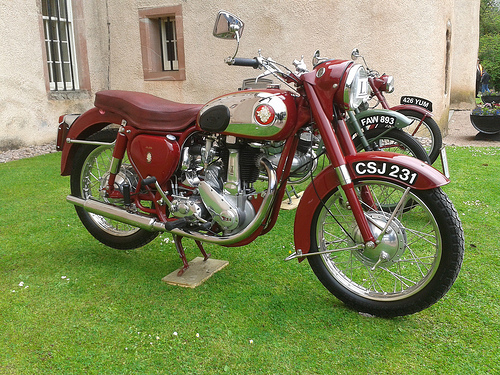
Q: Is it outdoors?
A: Yes, it is outdoors.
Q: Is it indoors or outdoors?
A: It is outdoors.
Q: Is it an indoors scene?
A: No, it is outdoors.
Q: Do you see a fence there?
A: No, there are no fences.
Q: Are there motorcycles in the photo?
A: Yes, there is a motorcycle.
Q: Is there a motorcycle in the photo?
A: Yes, there is a motorcycle.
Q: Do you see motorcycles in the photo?
A: Yes, there is a motorcycle.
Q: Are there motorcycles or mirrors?
A: Yes, there is a motorcycle.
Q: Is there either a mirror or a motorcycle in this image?
A: Yes, there is a motorcycle.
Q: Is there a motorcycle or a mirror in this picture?
A: Yes, there is a motorcycle.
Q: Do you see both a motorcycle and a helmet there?
A: No, there is a motorcycle but no helmets.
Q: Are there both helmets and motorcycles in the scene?
A: No, there is a motorcycle but no helmets.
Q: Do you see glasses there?
A: No, there are no glasses.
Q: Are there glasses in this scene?
A: No, there are no glasses.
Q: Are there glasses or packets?
A: No, there are no glasses or packets.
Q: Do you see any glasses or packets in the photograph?
A: No, there are no glasses or packets.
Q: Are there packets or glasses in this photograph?
A: No, there are no glasses or packets.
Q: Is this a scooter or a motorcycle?
A: This is a motorcycle.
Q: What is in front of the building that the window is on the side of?
A: The motorbike is in front of the building.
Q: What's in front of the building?
A: The motorbike is in front of the building.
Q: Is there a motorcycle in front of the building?
A: Yes, there is a motorcycle in front of the building.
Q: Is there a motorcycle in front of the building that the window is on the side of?
A: Yes, there is a motorcycle in front of the building.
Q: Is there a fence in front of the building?
A: No, there is a motorcycle in front of the building.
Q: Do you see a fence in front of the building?
A: No, there is a motorcycle in front of the building.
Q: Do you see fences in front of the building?
A: No, there is a motorcycle in front of the building.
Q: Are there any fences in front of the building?
A: No, there is a motorcycle in front of the building.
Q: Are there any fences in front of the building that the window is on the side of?
A: No, there is a motorcycle in front of the building.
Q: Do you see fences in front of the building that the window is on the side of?
A: No, there is a motorcycle in front of the building.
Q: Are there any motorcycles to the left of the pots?
A: Yes, there is a motorcycle to the left of the pots.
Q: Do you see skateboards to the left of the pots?
A: No, there is a motorcycle to the left of the pots.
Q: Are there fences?
A: No, there are no fences.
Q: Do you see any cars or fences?
A: No, there are no fences or cars.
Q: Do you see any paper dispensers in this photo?
A: No, there are no paper dispensers.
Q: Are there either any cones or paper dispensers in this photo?
A: No, there are no paper dispensers or cones.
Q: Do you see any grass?
A: Yes, there is grass.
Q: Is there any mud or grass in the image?
A: Yes, there is grass.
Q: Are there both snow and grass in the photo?
A: No, there is grass but no snow.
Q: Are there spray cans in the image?
A: No, there are no spray cans.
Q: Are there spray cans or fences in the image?
A: No, there are no spray cans or fences.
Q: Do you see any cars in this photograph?
A: No, there are no cars.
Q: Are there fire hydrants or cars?
A: No, there are no cars or fire hydrants.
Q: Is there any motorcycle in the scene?
A: Yes, there is a motorcycle.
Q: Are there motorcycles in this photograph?
A: Yes, there is a motorcycle.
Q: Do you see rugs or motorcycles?
A: Yes, there is a motorcycle.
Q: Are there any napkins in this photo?
A: No, there are no napkins.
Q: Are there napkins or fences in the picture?
A: No, there are no napkins or fences.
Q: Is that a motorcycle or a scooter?
A: That is a motorcycle.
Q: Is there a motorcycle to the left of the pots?
A: Yes, there is a motorcycle to the left of the pots.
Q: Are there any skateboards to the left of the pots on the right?
A: No, there is a motorcycle to the left of the pots.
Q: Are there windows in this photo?
A: Yes, there is a window.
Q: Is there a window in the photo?
A: Yes, there is a window.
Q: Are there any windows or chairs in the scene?
A: Yes, there is a window.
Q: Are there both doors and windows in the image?
A: No, there is a window but no doors.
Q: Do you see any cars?
A: No, there are no cars.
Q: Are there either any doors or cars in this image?
A: No, there are no cars or doors.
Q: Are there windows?
A: Yes, there is a window.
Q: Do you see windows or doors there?
A: Yes, there is a window.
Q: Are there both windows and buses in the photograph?
A: No, there is a window but no buses.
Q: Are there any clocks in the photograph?
A: No, there are no clocks.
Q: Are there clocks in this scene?
A: No, there are no clocks.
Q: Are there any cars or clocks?
A: No, there are no clocks or cars.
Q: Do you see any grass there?
A: Yes, there is grass.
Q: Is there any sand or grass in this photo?
A: Yes, there is grass.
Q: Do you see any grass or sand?
A: Yes, there is grass.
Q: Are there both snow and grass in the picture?
A: No, there is grass but no snow.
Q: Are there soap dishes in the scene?
A: No, there are no soap dishes.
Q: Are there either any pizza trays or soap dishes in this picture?
A: No, there are no soap dishes or pizza trays.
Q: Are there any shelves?
A: No, there are no shelves.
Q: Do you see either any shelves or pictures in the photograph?
A: No, there are no shelves or pictures.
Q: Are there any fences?
A: No, there are no fences.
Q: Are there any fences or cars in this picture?
A: No, there are no fences or cars.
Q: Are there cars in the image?
A: No, there are no cars.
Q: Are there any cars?
A: No, there are no cars.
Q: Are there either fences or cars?
A: No, there are no cars or fences.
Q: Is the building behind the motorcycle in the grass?
A: Yes, the building is behind the motorcycle.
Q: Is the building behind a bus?
A: No, the building is behind the motorcycle.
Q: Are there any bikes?
A: Yes, there is a bike.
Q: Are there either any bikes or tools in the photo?
A: Yes, there is a bike.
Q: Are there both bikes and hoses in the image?
A: No, there is a bike but no hoses.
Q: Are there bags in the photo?
A: No, there are no bags.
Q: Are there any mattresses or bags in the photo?
A: No, there are no bags or mattresses.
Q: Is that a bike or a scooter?
A: That is a bike.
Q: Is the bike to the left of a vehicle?
A: No, the bike is to the left of a man.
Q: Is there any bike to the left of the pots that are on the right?
A: Yes, there is a bike to the left of the pots.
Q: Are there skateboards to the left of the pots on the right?
A: No, there is a bike to the left of the pots.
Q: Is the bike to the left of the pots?
A: Yes, the bike is to the left of the pots.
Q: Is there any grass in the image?
A: Yes, there is grass.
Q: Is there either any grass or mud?
A: Yes, there is grass.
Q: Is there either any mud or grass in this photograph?
A: Yes, there is grass.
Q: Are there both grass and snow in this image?
A: No, there is grass but no snow.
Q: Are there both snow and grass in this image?
A: No, there is grass but no snow.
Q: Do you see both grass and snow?
A: No, there is grass but no snow.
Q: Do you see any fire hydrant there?
A: No, there are no fire hydrants.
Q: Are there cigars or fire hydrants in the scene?
A: No, there are no fire hydrants or cigars.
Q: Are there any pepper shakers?
A: No, there are no pepper shakers.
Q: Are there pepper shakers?
A: No, there are no pepper shakers.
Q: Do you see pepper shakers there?
A: No, there are no pepper shakers.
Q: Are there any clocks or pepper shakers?
A: No, there are no pepper shakers or clocks.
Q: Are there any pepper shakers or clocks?
A: No, there are no pepper shakers or clocks.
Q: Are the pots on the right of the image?
A: Yes, the pots are on the right of the image.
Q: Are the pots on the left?
A: No, the pots are on the right of the image.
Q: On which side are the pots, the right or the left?
A: The pots are on the right of the image.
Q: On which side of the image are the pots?
A: The pots are on the right of the image.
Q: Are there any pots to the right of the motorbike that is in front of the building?
A: Yes, there are pots to the right of the motorbike.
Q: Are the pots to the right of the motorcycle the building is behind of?
A: Yes, the pots are to the right of the motorcycle.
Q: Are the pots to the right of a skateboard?
A: No, the pots are to the right of the motorcycle.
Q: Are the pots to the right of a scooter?
A: No, the pots are to the right of the bike.